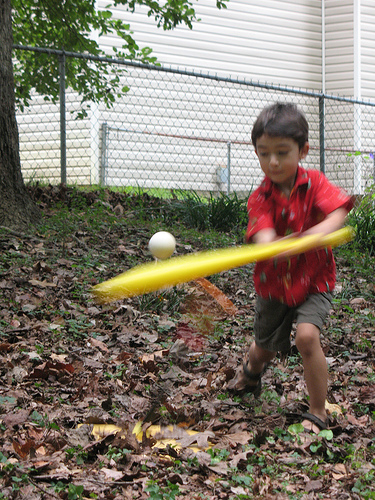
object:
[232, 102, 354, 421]
boy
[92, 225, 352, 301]
bat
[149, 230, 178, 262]
ball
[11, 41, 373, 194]
house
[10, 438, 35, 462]
leaves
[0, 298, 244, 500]
ground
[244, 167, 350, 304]
shirt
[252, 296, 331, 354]
shorts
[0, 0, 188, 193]
tree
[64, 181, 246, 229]
grass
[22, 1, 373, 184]
home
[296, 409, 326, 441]
sandal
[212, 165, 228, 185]
box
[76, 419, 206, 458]
object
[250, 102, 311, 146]
hair